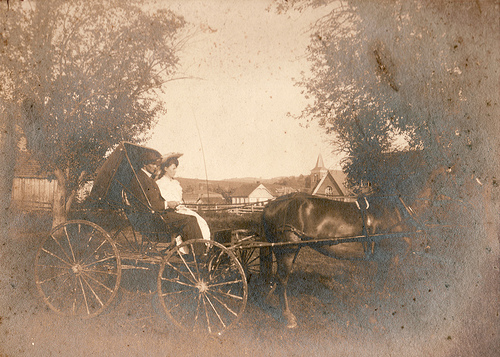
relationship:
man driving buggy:
[126, 152, 219, 264] [40, 149, 275, 301]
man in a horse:
[126, 152, 219, 264] [253, 158, 480, 335]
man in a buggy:
[126, 152, 219, 264] [21, 137, 258, 338]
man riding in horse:
[126, 152, 219, 264] [250, 162, 498, 344]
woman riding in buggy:
[155, 152, 210, 256] [20, 135, 280, 331]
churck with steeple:
[309, 151, 363, 206] [308, 151, 331, 189]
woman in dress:
[155, 152, 210, 256] [155, 175, 209, 239]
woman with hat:
[155, 152, 210, 256] [157, 151, 182, 163]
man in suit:
[130, 151, 220, 263] [122, 167, 207, 255]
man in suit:
[126, 152, 219, 264] [128, 166, 209, 255]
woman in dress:
[157, 171, 209, 237] [147, 172, 211, 251]